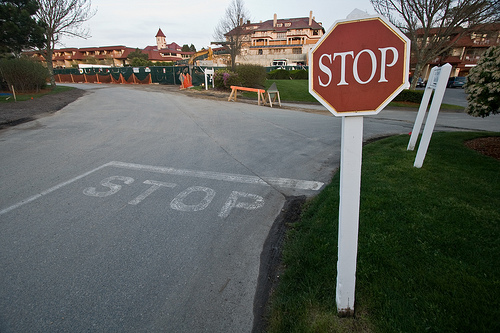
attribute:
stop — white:
[316, 44, 400, 88]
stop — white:
[85, 166, 267, 223]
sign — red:
[303, 13, 418, 115]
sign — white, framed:
[406, 63, 455, 169]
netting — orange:
[55, 71, 155, 84]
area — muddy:
[0, 94, 73, 125]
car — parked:
[450, 73, 466, 90]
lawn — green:
[398, 191, 496, 294]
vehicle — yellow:
[186, 46, 217, 66]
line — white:
[0, 155, 86, 224]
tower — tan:
[154, 28, 167, 49]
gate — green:
[154, 67, 178, 85]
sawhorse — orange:
[228, 82, 265, 104]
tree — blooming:
[467, 49, 500, 113]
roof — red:
[81, 45, 121, 50]